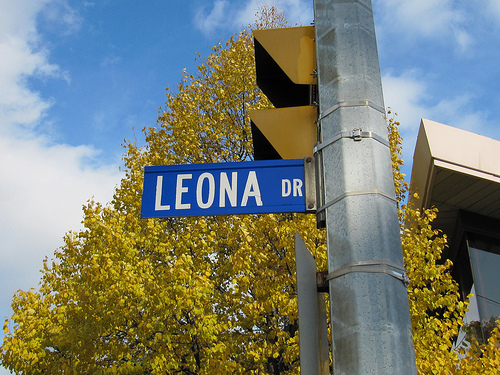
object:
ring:
[317, 189, 398, 212]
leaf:
[1, 317, 13, 333]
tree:
[125, 45, 359, 355]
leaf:
[162, 122, 167, 127]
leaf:
[395, 112, 399, 116]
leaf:
[272, 352, 279, 359]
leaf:
[467, 293, 475, 298]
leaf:
[413, 192, 418, 199]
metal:
[313, 0, 418, 375]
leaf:
[429, 205, 439, 215]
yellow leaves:
[5, 7, 498, 371]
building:
[406, 118, 499, 364]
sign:
[140, 160, 307, 218]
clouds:
[24, 119, 68, 216]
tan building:
[401, 117, 499, 373]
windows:
[462, 228, 499, 370]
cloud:
[4, 11, 124, 197]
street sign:
[138, 156, 319, 220]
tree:
[19, 3, 499, 355]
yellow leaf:
[452, 315, 464, 328]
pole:
[312, 0, 418, 375]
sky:
[98, 20, 195, 118]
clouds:
[3, 45, 62, 196]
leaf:
[164, 294, 186, 319]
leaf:
[201, 259, 212, 272]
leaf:
[196, 239, 208, 251]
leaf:
[107, 247, 141, 274]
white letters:
[153, 170, 263, 211]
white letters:
[281, 178, 303, 197]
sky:
[0, 1, 496, 118]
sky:
[4, 5, 497, 302]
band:
[312, 127, 393, 154]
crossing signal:
[249, 25, 318, 162]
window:
[451, 230, 500, 334]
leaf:
[411, 189, 422, 201]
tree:
[401, 188, 481, 368]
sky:
[39, 20, 252, 162]